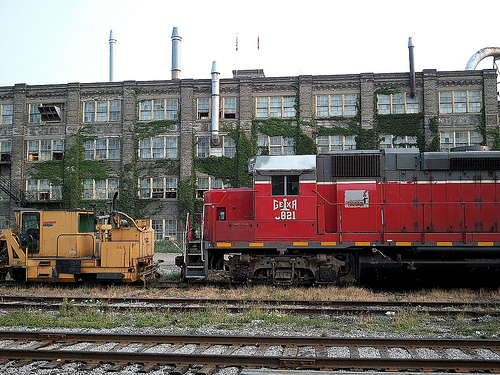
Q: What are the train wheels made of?
A: Steel.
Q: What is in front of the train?
A: Yellow vehicle.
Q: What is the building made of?
A: Brick.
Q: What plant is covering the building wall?
A: Vines.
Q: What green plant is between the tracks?
A: Grass.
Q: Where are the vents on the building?
A: The roof.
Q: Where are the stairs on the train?
A: Front car.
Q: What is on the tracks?
A: A train.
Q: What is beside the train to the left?
A: Tracks.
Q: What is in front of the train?
A: A tractor.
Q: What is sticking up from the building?
A: Metal poles.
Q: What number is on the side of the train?
A: 821.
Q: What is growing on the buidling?
A: Vines.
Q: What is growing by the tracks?
A: Grass.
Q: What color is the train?
A: Red.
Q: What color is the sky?
A: White.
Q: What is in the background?
A: A building.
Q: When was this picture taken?
A: Daytime.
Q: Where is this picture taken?
A: A train depot.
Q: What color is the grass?
A: Green.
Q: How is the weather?
A: Clear.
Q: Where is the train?
A: On the train tracks.